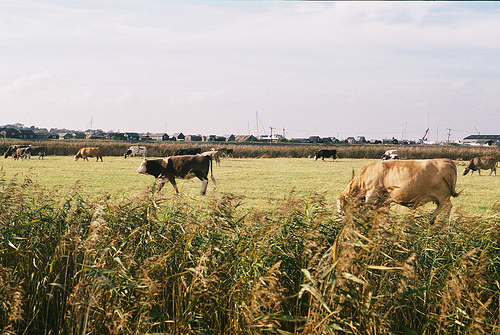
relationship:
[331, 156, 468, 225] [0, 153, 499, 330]
cow standing in field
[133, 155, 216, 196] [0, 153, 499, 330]
cow standing in field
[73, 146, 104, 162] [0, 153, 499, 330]
cow standing in field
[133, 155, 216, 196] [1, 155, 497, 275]
cow in field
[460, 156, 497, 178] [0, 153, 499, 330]
cow standing in field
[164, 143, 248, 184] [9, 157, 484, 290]
cow standing in field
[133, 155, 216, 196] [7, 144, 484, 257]
cow standing in field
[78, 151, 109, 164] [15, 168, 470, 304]
cow standing in field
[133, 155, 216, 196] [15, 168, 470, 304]
cow standing in field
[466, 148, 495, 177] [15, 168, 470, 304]
cow standing in field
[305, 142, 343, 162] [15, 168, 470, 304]
cow standing in field